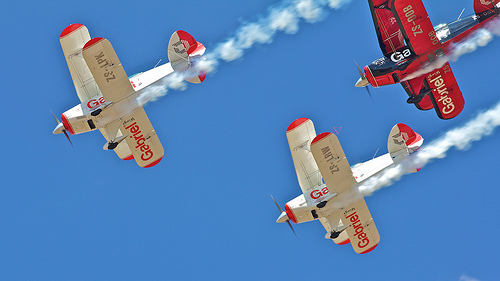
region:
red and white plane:
[45, 19, 200, 169]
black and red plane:
[356, 0, 499, 122]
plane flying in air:
[273, 113, 418, 249]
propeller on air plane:
[51, 112, 72, 144]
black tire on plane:
[106, 140, 119, 151]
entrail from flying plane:
[405, 12, 498, 84]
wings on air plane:
[58, 23, 165, 169]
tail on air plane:
[389, 120, 424, 170]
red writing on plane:
[128, 122, 154, 163]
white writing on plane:
[434, 73, 455, 116]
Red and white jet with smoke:
[24, 18, 224, 183]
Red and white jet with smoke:
[247, 106, 482, 271]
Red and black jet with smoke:
[343, 3, 494, 123]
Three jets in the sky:
[40, 12, 497, 255]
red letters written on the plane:
[341, 209, 376, 251]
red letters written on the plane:
[117, 118, 155, 166]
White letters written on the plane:
[426, 71, 461, 117]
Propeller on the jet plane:
[26, 106, 86, 160]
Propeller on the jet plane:
[256, 181, 300, 246]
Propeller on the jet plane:
[330, 52, 380, 114]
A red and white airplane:
[35, 15, 222, 167]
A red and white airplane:
[273, 110, 428, 255]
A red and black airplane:
[348, 0, 498, 118]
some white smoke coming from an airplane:
[85, 0, 346, 122]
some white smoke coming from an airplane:
[317, 105, 497, 210]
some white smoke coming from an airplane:
[400, 16, 496, 77]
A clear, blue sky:
[1, 2, 496, 277]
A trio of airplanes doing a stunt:
[43, 2, 499, 252]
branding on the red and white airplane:
[120, 110, 156, 163]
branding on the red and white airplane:
[342, 207, 377, 252]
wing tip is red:
[61, 23, 83, 36]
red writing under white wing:
[126, 122, 153, 162]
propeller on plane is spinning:
[50, 108, 76, 146]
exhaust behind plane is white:
[144, 1, 347, 101]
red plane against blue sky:
[356, 0, 499, 119]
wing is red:
[392, 0, 441, 57]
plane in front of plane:
[275, 117, 439, 254]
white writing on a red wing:
[430, 71, 457, 118]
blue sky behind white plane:
[1, 5, 499, 280]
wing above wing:
[287, 116, 328, 186]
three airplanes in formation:
[20, 22, 456, 230]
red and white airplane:
[42, 37, 242, 148]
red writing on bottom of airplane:
[104, 78, 165, 182]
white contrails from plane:
[119, 9, 319, 126]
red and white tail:
[146, 11, 233, 96]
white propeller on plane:
[37, 100, 82, 154]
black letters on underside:
[82, 53, 123, 100]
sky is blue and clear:
[72, 147, 195, 277]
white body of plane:
[93, 66, 188, 111]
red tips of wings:
[59, 30, 115, 80]